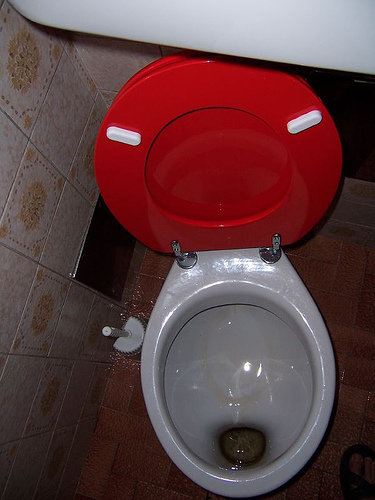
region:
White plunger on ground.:
[104, 310, 136, 361]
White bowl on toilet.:
[141, 366, 312, 473]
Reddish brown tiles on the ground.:
[95, 441, 153, 485]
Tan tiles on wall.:
[17, 361, 59, 414]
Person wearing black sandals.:
[339, 458, 358, 483]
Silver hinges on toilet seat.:
[163, 232, 294, 278]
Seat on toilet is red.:
[125, 98, 325, 221]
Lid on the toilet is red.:
[187, 125, 247, 187]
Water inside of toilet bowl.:
[215, 424, 267, 466]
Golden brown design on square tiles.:
[34, 370, 66, 415]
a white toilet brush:
[99, 315, 143, 356]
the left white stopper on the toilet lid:
[105, 126, 142, 149]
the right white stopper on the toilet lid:
[285, 107, 321, 135]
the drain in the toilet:
[212, 424, 268, 465]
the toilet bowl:
[162, 300, 314, 469]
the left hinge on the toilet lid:
[169, 238, 202, 270]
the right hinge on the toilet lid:
[258, 230, 282, 265]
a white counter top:
[10, 1, 374, 74]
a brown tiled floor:
[74, 233, 371, 497]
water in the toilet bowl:
[175, 358, 307, 458]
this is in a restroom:
[5, 4, 370, 320]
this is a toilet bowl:
[129, 298, 325, 482]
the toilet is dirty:
[221, 415, 283, 463]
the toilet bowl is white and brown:
[153, 318, 315, 483]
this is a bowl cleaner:
[100, 308, 175, 386]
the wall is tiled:
[18, 292, 105, 435]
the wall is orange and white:
[3, 275, 114, 399]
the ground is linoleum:
[95, 410, 159, 483]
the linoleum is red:
[87, 411, 195, 496]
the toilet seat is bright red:
[103, 94, 360, 212]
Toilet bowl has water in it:
[208, 409, 302, 485]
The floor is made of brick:
[102, 444, 182, 497]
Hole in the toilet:
[221, 421, 287, 459]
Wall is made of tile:
[21, 266, 104, 390]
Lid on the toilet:
[96, 76, 325, 252]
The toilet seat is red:
[115, 111, 251, 221]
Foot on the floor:
[342, 439, 374, 489]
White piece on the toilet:
[285, 106, 335, 149]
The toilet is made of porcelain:
[168, 275, 185, 300]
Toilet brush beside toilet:
[92, 306, 167, 367]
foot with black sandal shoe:
[338, 443, 373, 497]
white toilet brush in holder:
[103, 316, 146, 355]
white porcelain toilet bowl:
[139, 243, 337, 498]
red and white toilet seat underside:
[94, 51, 344, 254]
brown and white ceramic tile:
[1, 140, 67, 261]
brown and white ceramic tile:
[0, 0, 64, 135]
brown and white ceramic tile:
[8, 264, 72, 357]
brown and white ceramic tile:
[22, 358, 73, 436]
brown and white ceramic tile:
[32, 422, 80, 498]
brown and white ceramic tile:
[80, 362, 111, 420]